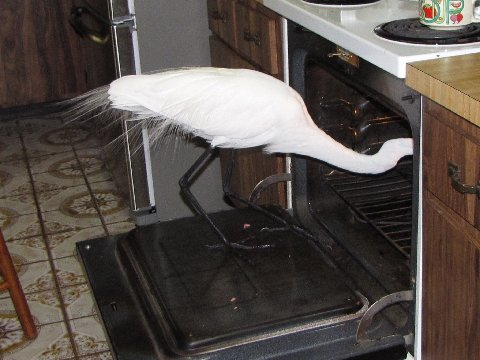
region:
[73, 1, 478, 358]
white oven and stove with open door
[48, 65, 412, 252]
white crane looking inside kitchen oven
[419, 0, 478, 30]
white mug with vegetables painted on side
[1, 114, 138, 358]
beige and gold linoleum kitchen floor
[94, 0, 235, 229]
gray refrigerator door with metal handle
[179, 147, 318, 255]
bird has black legs that bend backwards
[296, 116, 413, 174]
bird's long neck partially sticking inside of oven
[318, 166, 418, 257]
metal oven rack is in lowest position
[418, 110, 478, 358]
dark wooden cabinet and drawer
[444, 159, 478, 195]
cabinet hardware is black metal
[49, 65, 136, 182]
Soft bird white feathers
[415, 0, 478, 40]
coffee mug on stove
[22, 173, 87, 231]
old floor from long time ago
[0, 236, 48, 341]
bar stool leg wood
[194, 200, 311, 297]
large bird feet all blacked out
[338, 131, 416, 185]
bird neck on s bend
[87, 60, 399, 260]
Large bird white black feet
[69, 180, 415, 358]
open stove with bird on it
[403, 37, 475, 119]
old cheep counter wrapped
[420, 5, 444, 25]
red logo on old cup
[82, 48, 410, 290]
white bird standing on an open oven door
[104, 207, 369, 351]
open oven door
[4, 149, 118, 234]
brown and white kitchen linoleum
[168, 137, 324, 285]
black feet of standing bird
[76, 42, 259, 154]
feather of a white bird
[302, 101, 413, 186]
neck of a white bird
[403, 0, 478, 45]
ceramic dish on a stove burner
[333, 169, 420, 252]
black metal oven rack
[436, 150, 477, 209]
kitchen drawer pull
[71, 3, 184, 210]
refrigerator and freezer in a kitchen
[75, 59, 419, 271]
a crane looking into an open oven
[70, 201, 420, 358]
the door of the oven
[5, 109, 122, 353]
the tile floor next to the appliances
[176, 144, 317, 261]
the legs of the bird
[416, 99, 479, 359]
the cabinets next to the oven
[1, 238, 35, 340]
the wooden leg of a chair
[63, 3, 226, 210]
the fridge sitting next to the cabinet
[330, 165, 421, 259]
the metal rack sitting in the oven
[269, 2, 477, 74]
the stove sitting on top of the oven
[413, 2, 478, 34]
a cup sitting on the burner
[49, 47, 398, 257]
A goose with it's head in the oven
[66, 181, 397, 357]
The oven door is open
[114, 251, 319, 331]
The inside of the oven is dark gray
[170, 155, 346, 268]
The legs of the goose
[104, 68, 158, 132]
The tail of the goose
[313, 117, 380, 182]
The neck of the goose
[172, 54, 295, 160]
The body of the goose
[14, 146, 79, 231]
The floor is made of tile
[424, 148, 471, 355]
The cabinet is made of wood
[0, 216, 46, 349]
The wooden leg of a chair